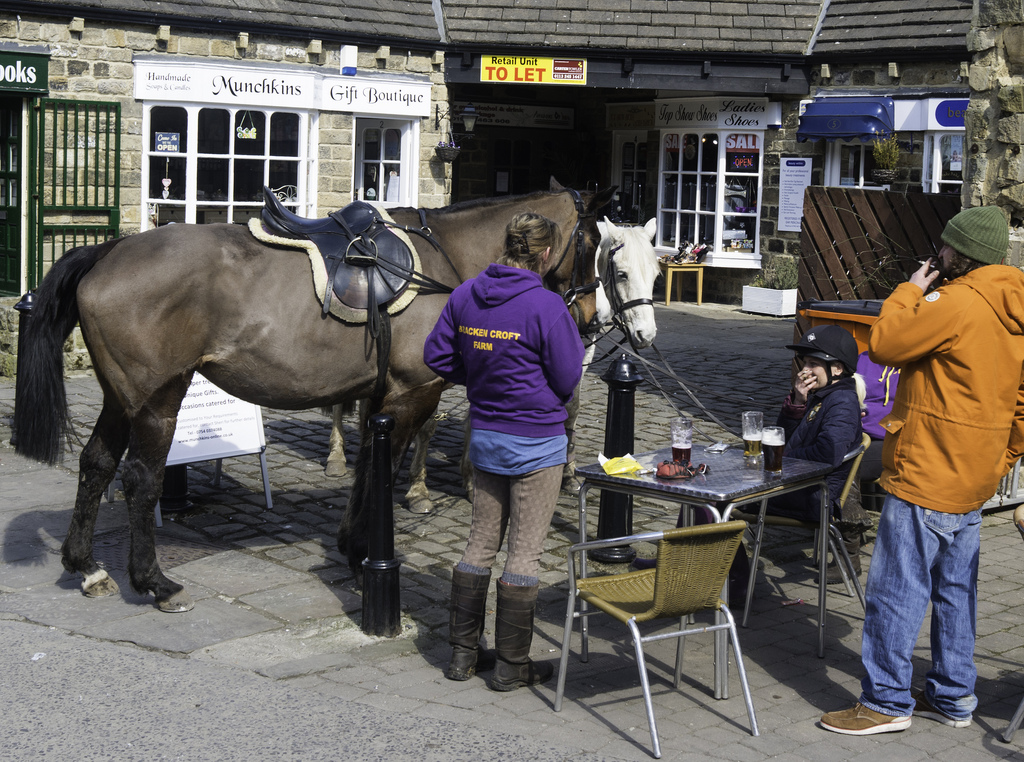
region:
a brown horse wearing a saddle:
[9, 173, 621, 613]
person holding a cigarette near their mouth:
[818, 204, 1022, 735]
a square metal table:
[571, 440, 829, 666]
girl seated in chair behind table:
[571, 323, 867, 663]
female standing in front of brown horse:
[8, 175, 623, 692]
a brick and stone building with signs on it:
[2, 4, 1021, 381]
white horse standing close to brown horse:
[12, 173, 662, 611]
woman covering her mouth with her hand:
[676, 323, 867, 609]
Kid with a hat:
[777, 319, 864, 531]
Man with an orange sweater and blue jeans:
[809, 202, 1022, 743]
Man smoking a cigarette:
[814, 205, 1017, 737]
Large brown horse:
[13, 173, 637, 619]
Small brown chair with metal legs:
[541, 519, 761, 754]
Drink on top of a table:
[757, 423, 790, 480]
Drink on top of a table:
[664, 414, 697, 463]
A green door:
[0, 91, 38, 291]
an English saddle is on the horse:
[239, 179, 423, 341]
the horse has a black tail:
[10, 231, 132, 465]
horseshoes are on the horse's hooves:
[66, 568, 203, 617]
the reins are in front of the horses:
[632, 339, 747, 441]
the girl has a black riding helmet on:
[789, 326, 862, 404]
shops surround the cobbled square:
[8, 0, 1023, 402]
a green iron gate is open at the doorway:
[6, 72, 120, 335]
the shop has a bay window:
[653, 114, 771, 274]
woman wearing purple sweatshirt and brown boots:
[423, 209, 592, 693]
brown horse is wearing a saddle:
[13, 171, 623, 614]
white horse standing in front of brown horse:
[8, 173, 667, 600]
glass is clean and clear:
[383, 122, 403, 161]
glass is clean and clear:
[376, 161, 397, 200]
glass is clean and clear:
[361, 161, 378, 197]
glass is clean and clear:
[266, 157, 295, 202]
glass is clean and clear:
[228, 157, 261, 197]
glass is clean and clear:
[199, 154, 232, 205]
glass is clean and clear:
[149, 151, 185, 197]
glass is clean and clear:
[147, 106, 187, 151]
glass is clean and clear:
[196, 106, 229, 157]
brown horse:
[59, 148, 592, 602]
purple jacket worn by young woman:
[450, 257, 572, 442]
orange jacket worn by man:
[887, 267, 1021, 470]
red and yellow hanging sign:
[463, 43, 606, 89]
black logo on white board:
[156, 63, 422, 111]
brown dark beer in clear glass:
[672, 415, 696, 467]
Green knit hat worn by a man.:
[934, 201, 1007, 260]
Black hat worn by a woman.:
[779, 322, 862, 384]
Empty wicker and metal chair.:
[545, 519, 762, 754]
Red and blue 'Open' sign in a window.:
[727, 152, 757, 171]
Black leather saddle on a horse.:
[250, 188, 413, 315]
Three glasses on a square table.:
[662, 409, 789, 467]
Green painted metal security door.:
[33, 96, 117, 318]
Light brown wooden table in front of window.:
[655, 251, 706, 305]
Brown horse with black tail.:
[5, 176, 620, 616]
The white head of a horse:
[590, 191, 666, 398]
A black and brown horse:
[24, 185, 629, 701]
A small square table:
[580, 424, 846, 677]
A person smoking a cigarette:
[845, 204, 992, 758]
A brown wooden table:
[658, 257, 713, 314]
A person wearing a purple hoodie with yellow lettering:
[429, 215, 589, 693]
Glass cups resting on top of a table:
[666, 405, 797, 481]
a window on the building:
[166, 95, 209, 206]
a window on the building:
[345, 121, 415, 223]